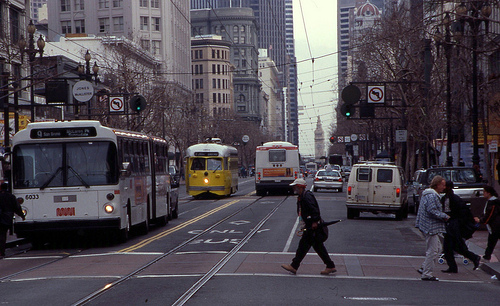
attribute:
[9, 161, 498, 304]
road — busy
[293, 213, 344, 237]
umbrella — dark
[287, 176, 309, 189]
cap — white, tan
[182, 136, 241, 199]
streetcar — yellow, white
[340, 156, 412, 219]
van — white, cream colored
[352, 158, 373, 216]
ladder — silver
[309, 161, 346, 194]
cab — white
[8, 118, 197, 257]
bus — white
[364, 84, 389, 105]
sign — red white, black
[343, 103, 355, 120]
light — green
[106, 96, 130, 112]
sign — no left turn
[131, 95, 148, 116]
light — green